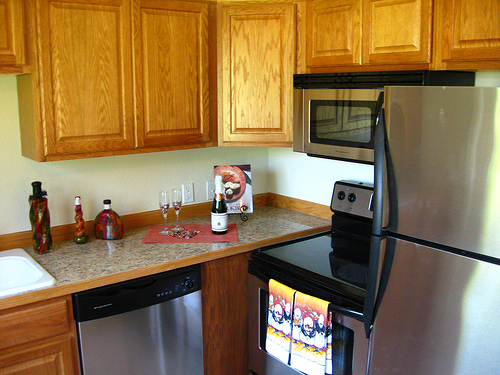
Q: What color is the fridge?
A: Silver.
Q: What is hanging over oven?
A: Towels.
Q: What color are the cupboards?
A: Brown.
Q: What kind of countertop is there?
A: Granite.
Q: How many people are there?
A: None.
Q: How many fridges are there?
A: One.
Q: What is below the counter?
A: Dishwasher.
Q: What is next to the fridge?
A: Microwave.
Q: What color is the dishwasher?
A: Grey.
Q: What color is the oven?
A: Gray.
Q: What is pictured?
A: A kitchen.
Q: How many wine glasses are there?
A: Two.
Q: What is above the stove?
A: Microwave.